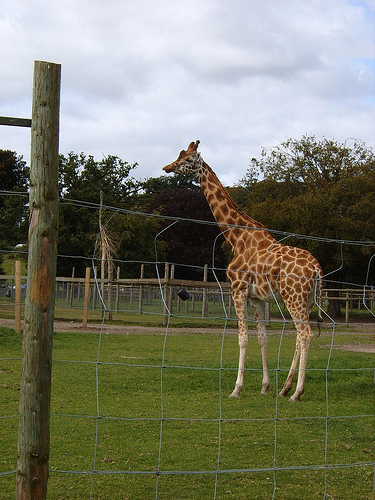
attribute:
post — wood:
[16, 59, 60, 498]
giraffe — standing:
[160, 135, 333, 410]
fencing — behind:
[60, 260, 371, 324]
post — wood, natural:
[12, 47, 67, 497]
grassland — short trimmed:
[5, 321, 371, 498]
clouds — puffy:
[2, 1, 373, 189]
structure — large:
[72, 211, 369, 361]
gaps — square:
[95, 361, 164, 418]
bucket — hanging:
[174, 283, 195, 302]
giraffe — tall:
[168, 99, 312, 388]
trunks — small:
[27, 49, 73, 200]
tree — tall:
[237, 129, 374, 184]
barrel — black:
[174, 285, 191, 303]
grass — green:
[1, 296, 372, 499]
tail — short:
[312, 260, 324, 340]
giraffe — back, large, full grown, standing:
[162, 138, 324, 401]